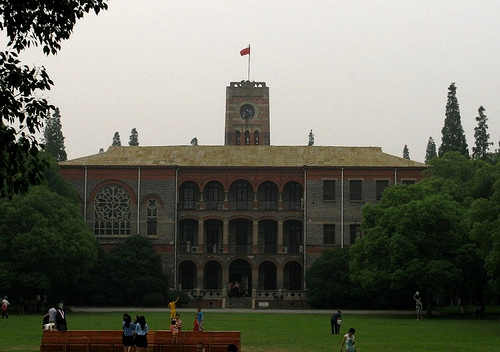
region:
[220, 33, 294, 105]
red flag on top on building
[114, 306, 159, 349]
four girls wearing blue uniforms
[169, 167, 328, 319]
front of building with archways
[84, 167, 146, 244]
decorative window coverings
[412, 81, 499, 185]
tall evergreen trees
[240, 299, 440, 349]
bright green grass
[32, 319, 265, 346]
wooden bench outside large building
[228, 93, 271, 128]
clock on front of brick building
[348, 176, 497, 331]
green leaves on tree int he spring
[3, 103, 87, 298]
green leaves on tree in the spring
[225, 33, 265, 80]
The building has a flag.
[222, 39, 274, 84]
The flag is red.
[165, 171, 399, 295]
The building has many windows.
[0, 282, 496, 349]
The building looks out onto a lawn.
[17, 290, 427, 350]
People are walking on the lawn.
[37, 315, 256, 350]
Benches are on the lawn.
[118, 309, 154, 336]
The two girls wear blue tops.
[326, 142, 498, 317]
Trees are in front of the building.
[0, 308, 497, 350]
The lawn is lush and green.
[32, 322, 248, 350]
The benches are red.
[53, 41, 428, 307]
a stone building with a flag on top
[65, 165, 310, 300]
the building has arched windows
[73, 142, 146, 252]
the building has a stained glass window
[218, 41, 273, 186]
a bell tower is on top of the building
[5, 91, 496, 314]
tall trees surround the building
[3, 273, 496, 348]
the building has a grassy area in front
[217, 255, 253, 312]
the front entrance has a stairway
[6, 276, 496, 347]
people are walking around the grassy area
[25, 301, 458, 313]
a side walk is in front of the building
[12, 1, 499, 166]
the sky is gray behind the building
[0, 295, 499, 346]
large green lawn in front of building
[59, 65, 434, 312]
large Gothic institutional building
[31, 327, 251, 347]
red benches on lawn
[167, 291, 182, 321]
man in yellow shirt with arm raised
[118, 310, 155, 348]
two girls with long dark hair standing behind bench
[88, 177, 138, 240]
arched Gothic window with lattice work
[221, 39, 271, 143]
clock tower with red flag flying on top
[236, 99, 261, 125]
black clock face in brick tower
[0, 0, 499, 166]
clear white bright daytime sky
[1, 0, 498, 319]
lush green trees lining lawn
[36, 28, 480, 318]
Old building with a tower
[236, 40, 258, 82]
Red flag on top of building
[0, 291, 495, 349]
People in the yard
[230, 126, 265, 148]
Three narrow windows on the tower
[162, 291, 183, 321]
Person wearing yellow cloths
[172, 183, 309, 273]
Large balconies in the building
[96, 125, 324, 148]
Canopy of trees behind building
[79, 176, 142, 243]
Big window on left side of building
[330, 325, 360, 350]
Person wearing a white t-shirt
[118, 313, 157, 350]
Two woman standing together